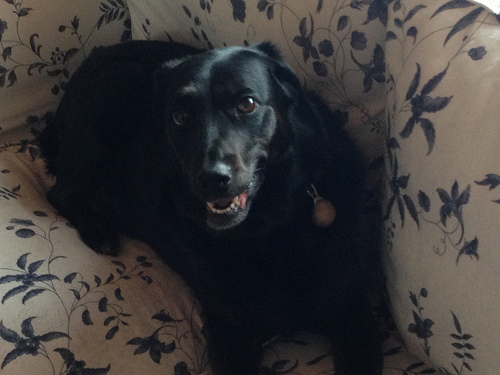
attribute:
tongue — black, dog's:
[233, 191, 245, 209]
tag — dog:
[296, 180, 336, 226]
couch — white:
[8, 0, 495, 374]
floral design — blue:
[438, 176, 467, 236]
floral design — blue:
[357, 52, 388, 89]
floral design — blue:
[403, 306, 435, 352]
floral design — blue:
[131, 318, 170, 362]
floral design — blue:
[2, 250, 52, 310]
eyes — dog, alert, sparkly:
[129, 81, 301, 132]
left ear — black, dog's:
[263, 64, 332, 151]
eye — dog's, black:
[170, 102, 191, 128]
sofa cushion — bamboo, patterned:
[3, 115, 304, 374]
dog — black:
[33, 38, 383, 373]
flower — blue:
[4, 312, 73, 374]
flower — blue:
[291, 15, 325, 62]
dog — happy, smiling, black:
[35, 28, 411, 373]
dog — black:
[144, 50, 389, 230]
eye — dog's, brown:
[237, 96, 255, 111]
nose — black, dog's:
[174, 133, 269, 190]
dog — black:
[44, 16, 439, 372]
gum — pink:
[239, 192, 249, 209]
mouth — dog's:
[203, 185, 258, 226]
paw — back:
[58, 186, 128, 266]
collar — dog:
[152, 66, 346, 229]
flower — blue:
[392, 64, 456, 153]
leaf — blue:
[443, 307, 465, 335]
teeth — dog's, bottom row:
[203, 180, 252, 219]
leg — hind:
[40, 156, 140, 262]